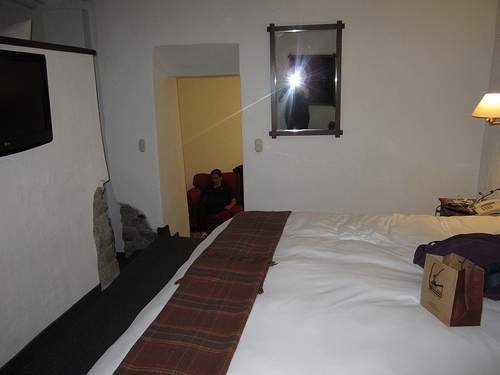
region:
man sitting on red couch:
[188, 160, 245, 240]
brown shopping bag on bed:
[421, 235, 486, 340]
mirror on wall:
[264, 13, 356, 153]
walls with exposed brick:
[87, 168, 169, 290]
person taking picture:
[253, 17, 352, 149]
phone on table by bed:
[433, 189, 498, 216]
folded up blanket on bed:
[89, 198, 498, 371]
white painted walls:
[98, 12, 499, 209]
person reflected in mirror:
[258, 15, 357, 140]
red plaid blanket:
[118, 203, 278, 370]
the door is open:
[154, 48, 241, 205]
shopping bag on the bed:
[414, 238, 498, 324]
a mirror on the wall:
[263, 21, 351, 151]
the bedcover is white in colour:
[309, 232, 355, 358]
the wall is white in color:
[384, 53, 416, 105]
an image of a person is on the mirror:
[281, 51, 321, 128]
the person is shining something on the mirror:
[279, 70, 317, 109]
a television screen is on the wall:
[1, 63, 51, 150]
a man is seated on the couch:
[204, 170, 228, 211]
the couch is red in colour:
[188, 171, 240, 216]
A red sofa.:
[186, 172, 245, 230]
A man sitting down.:
[189, 167, 239, 234]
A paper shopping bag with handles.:
[419, 251, 486, 329]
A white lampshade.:
[470, 91, 498, 118]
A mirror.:
[272, 47, 347, 138]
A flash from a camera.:
[274, 49, 309, 104]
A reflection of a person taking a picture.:
[274, 54, 314, 130]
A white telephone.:
[471, 198, 498, 219]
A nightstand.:
[437, 189, 497, 222]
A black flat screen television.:
[1, 52, 54, 163]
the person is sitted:
[191, 167, 238, 217]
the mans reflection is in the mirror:
[277, 38, 349, 140]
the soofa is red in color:
[190, 168, 245, 216]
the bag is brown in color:
[423, 243, 486, 329]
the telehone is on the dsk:
[452, 168, 499, 218]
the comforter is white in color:
[293, 213, 400, 374]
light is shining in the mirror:
[272, 53, 322, 105]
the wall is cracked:
[89, 191, 144, 278]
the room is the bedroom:
[8, 18, 490, 374]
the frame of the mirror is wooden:
[257, 24, 351, 151]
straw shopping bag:
[415, 249, 487, 328]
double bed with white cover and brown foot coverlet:
[89, 204, 498, 373]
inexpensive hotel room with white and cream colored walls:
[4, 3, 495, 373]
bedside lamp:
[471, 87, 498, 192]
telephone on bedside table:
[472, 194, 499, 211]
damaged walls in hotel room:
[87, 176, 185, 261]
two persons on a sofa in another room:
[183, 160, 248, 238]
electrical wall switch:
[252, 136, 263, 153]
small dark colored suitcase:
[411, 229, 498, 304]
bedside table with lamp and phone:
[437, 89, 497, 220]